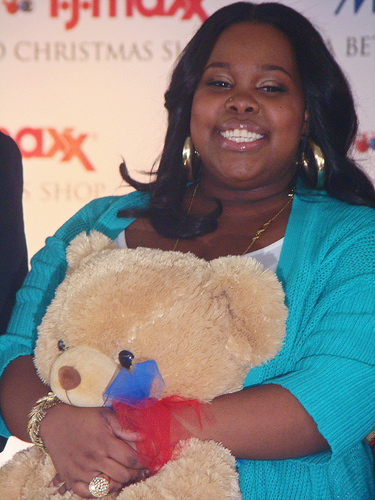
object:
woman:
[0, 0, 375, 499]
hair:
[113, 1, 375, 241]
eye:
[119, 350, 134, 370]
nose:
[58, 365, 81, 390]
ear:
[210, 252, 290, 369]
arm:
[0, 446, 55, 498]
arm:
[0, 197, 131, 445]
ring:
[88, 476, 110, 499]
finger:
[74, 478, 126, 495]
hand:
[40, 398, 160, 499]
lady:
[0, 0, 375, 499]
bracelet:
[26, 390, 63, 448]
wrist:
[26, 381, 59, 455]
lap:
[42, 397, 151, 499]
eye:
[57, 337, 68, 352]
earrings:
[301, 139, 327, 190]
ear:
[299, 108, 310, 141]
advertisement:
[50, 0, 208, 31]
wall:
[0, 0, 375, 272]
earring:
[182, 137, 195, 182]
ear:
[187, 95, 192, 130]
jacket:
[0, 176, 375, 500]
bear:
[0, 229, 289, 499]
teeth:
[213, 127, 271, 150]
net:
[102, 358, 217, 473]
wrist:
[138, 397, 201, 469]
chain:
[242, 191, 295, 255]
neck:
[190, 165, 293, 215]